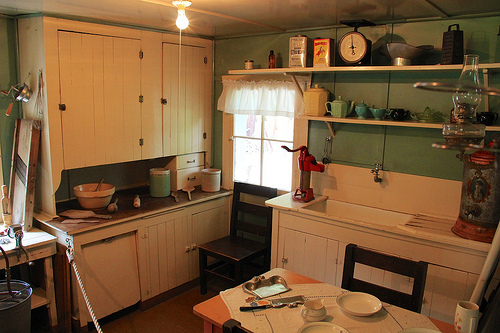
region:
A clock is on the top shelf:
[337, 27, 373, 74]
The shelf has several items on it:
[223, 14, 492, 74]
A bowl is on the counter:
[71, 178, 117, 212]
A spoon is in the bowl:
[75, 177, 120, 207]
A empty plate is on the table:
[333, 284, 384, 319]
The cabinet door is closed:
[47, 22, 152, 167]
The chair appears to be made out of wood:
[346, 241, 428, 306]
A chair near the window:
[211, 149, 286, 279]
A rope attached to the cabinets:
[65, 239, 110, 329]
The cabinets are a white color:
[47, 22, 209, 157]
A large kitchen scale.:
[335, 18, 372, 66]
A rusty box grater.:
[439, 23, 464, 65]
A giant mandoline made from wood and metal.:
[7, 117, 40, 232]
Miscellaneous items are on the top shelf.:
[227, 18, 499, 73]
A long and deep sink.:
[301, 197, 412, 227]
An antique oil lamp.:
[441, 53, 486, 162]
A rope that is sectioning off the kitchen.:
[64, 237, 103, 332]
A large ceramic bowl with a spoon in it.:
[71, 177, 115, 212]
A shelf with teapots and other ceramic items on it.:
[297, 82, 498, 132]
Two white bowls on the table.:
[297, 291, 382, 331]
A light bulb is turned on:
[166, 2, 193, 37]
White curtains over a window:
[210, 70, 305, 195]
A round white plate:
[330, 285, 382, 320]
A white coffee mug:
[448, 294, 485, 331]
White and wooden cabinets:
[40, 13, 219, 172]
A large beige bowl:
[65, 175, 116, 210]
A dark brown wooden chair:
[190, 172, 282, 297]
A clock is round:
[330, 25, 370, 66]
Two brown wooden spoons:
[162, 180, 198, 207]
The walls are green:
[0, 8, 497, 208]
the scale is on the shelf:
[338, 15, 369, 74]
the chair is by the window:
[242, 178, 265, 200]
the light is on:
[172, 13, 194, 36]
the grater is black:
[443, 31, 455, 56]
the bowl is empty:
[351, 296, 367, 308]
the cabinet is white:
[95, 77, 117, 100]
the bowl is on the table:
[357, 307, 375, 320]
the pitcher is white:
[308, 304, 324, 317]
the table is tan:
[205, 302, 225, 314]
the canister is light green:
[154, 177, 167, 191]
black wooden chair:
[189, 177, 281, 301]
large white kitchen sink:
[256, 153, 495, 315]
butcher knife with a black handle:
[236, 291, 316, 315]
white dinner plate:
[332, 289, 385, 324]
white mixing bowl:
[69, 174, 116, 211]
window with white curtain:
[203, 70, 320, 198]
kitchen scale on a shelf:
[331, 15, 376, 72]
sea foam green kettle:
[315, 87, 357, 122]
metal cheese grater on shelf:
[434, 20, 471, 67]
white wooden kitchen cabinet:
[16, 17, 214, 181]